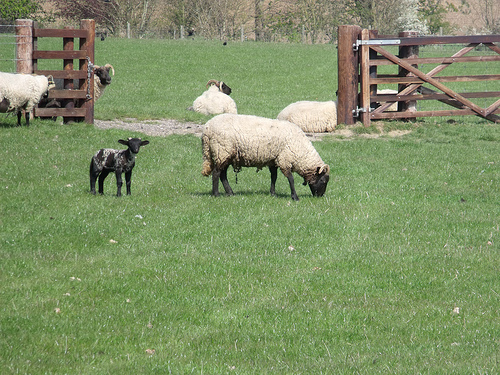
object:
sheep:
[200, 113, 330, 202]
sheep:
[0, 71, 56, 126]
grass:
[1, 34, 500, 373]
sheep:
[276, 99, 336, 133]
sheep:
[189, 79, 238, 114]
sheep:
[375, 89, 398, 112]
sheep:
[89, 137, 150, 197]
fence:
[336, 22, 499, 127]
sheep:
[92, 63, 114, 102]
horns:
[93, 63, 115, 76]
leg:
[284, 170, 297, 193]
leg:
[266, 164, 278, 193]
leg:
[221, 172, 233, 194]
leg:
[212, 167, 220, 192]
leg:
[24, 108, 30, 126]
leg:
[17, 107, 21, 124]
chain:
[85, 56, 96, 102]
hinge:
[352, 105, 375, 117]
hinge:
[353, 39, 402, 52]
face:
[308, 175, 330, 197]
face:
[222, 82, 233, 95]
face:
[96, 68, 111, 84]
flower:
[453, 307, 460, 314]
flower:
[288, 246, 294, 252]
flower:
[54, 308, 61, 314]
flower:
[109, 239, 119, 244]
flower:
[66, 183, 73, 187]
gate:
[360, 26, 499, 125]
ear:
[315, 164, 329, 175]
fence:
[0, 18, 96, 123]